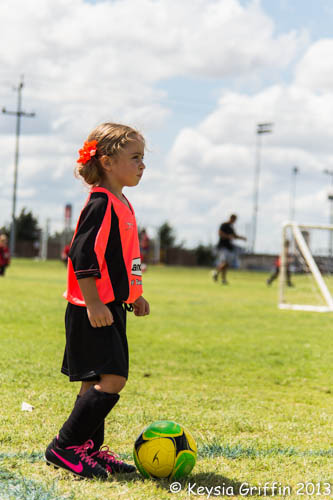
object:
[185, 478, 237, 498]
keysia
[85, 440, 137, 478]
soccer cleat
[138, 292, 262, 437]
ground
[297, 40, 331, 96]
cloud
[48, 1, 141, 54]
cloud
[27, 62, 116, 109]
cloud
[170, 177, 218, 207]
cloud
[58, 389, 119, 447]
shin guards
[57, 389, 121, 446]
black socks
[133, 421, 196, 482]
ball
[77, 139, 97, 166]
flower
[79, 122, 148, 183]
hair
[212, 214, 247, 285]
adult male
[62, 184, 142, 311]
jersey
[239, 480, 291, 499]
griffin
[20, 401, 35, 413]
trash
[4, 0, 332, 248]
sky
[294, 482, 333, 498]
number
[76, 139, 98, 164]
bow tie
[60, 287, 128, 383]
shorts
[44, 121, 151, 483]
girl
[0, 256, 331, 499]
field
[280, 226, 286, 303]
white post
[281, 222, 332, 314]
goal net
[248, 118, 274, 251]
stadium light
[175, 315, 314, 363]
grass field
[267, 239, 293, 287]
person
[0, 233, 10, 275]
person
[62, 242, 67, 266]
person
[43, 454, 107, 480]
cleats